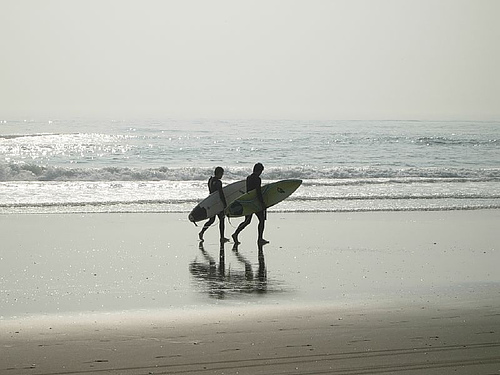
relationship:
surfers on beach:
[206, 156, 282, 248] [327, 223, 421, 282]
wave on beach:
[98, 148, 136, 188] [327, 223, 421, 282]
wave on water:
[98, 148, 136, 188] [240, 143, 276, 167]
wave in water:
[98, 148, 136, 188] [240, 143, 276, 167]